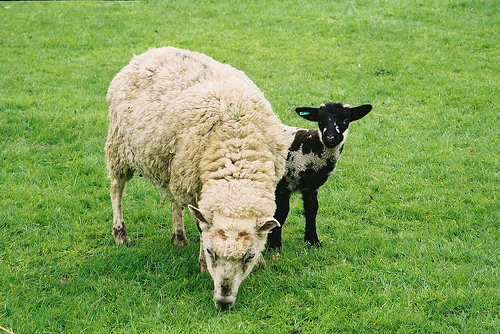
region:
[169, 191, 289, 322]
head of a sheep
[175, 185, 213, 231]
ear of a sheep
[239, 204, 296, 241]
ear of a sheep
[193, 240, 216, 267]
eye of a sheep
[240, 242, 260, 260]
eye of a sheep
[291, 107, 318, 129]
ear of a sheep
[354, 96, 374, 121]
ear of a sheep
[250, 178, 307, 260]
leg of a sheep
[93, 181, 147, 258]
leg of a sheep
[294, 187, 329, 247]
leg of a sheep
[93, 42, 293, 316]
an animal is eating grass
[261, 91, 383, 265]
a baby animal standing in grass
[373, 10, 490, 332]
a green grassy area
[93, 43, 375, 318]
two animals standing in the grass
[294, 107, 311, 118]
a blue ear tag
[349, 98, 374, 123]
the ear of an animal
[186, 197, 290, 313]
the head of an animal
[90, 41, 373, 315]
a baby animal with its mother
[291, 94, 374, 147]
the head of a baby animal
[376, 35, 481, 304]
The grass is short and green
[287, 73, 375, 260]
The goat is the color black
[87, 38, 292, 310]
The sheep is the color white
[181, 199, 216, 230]
The ear of the sheep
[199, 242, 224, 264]
The eye of the sheep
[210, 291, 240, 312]
The nose of the sheep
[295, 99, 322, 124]
The ear of the goat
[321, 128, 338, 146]
The nose of the goat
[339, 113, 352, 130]
The eye of the goat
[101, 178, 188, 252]
The legs of the sheep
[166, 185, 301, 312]
head of a sheep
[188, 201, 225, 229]
ear of a sheep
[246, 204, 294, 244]
ear of a sheep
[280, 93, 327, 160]
ear of a sheep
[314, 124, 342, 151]
mouth of a sheep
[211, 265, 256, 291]
nose of a sheep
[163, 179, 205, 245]
leg of a sheep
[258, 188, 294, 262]
leg of a sheep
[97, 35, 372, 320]
two animals standing together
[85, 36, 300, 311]
this is a sheep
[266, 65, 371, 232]
this is a goat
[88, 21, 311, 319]
the sheep is tan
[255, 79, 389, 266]
the goat is black and white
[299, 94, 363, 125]
ears on the goat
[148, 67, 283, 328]
the sheep is eating grass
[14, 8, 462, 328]
animals standing in green field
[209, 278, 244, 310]
black nose on sheep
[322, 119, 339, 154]
black nose on goat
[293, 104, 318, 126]
Ear of an animal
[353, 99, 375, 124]
Ear of an animal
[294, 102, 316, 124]
Ear of a black animal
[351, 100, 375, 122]
Ear of a black animal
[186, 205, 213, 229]
Ear of an animal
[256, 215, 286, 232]
Ear of an animal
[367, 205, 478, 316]
Patch of green grass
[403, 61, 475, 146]
Patch of green grass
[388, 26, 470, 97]
Patch of green grass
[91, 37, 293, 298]
white sheep in the field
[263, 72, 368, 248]
black sheep in the field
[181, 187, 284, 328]
sheep with its head in the grass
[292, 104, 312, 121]
blue tag on sheep ear